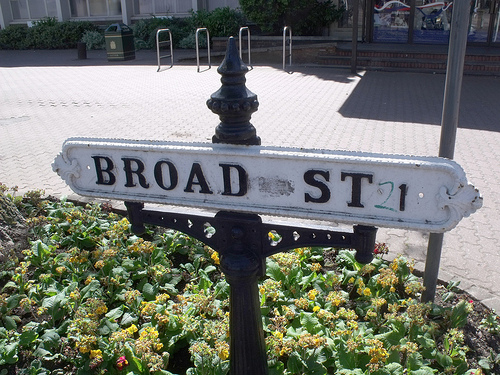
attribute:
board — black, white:
[38, 136, 473, 239]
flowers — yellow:
[25, 215, 222, 372]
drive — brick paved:
[0, 31, 498, 306]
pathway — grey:
[4, 57, 499, 310]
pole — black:
[199, 35, 271, 373]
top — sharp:
[199, 37, 267, 152]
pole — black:
[205, 210, 275, 374]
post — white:
[49, 135, 482, 233]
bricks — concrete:
[444, 243, 482, 274]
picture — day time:
[6, 4, 496, 371]